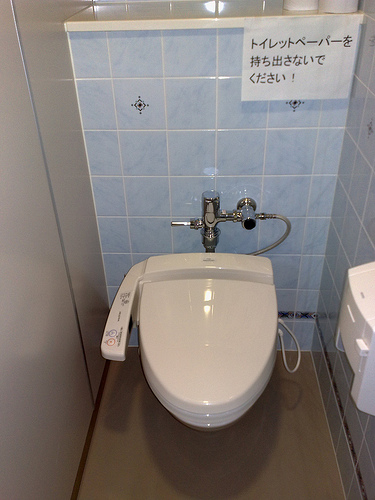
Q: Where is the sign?
A: On the wall.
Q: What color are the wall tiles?
A: Blue.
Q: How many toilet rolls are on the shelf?
A: Two.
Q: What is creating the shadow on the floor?
A: The toilet.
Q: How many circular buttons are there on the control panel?
A: Two.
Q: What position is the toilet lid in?
A: It is closed.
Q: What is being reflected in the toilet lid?
A: Light.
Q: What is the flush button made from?
A: Metal.